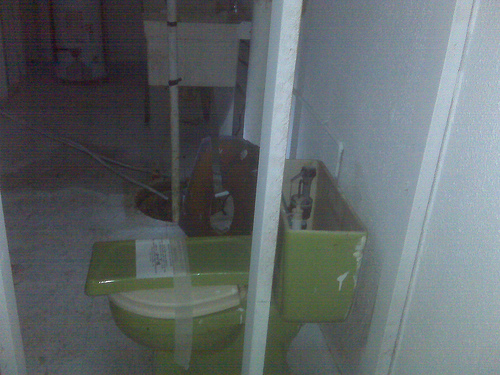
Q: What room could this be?
A: It is a bathroom.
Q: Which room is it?
A: It is a bathroom.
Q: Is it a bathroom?
A: Yes, it is a bathroom.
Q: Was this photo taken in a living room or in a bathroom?
A: It was taken at a bathroom.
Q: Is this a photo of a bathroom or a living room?
A: It is showing a bathroom.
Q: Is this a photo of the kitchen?
A: No, the picture is showing the bathroom.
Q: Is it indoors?
A: Yes, it is indoors.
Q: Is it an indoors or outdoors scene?
A: It is indoors.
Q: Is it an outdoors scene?
A: No, it is indoors.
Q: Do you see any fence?
A: No, there are no fences.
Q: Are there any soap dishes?
A: No, there are no soap dishes.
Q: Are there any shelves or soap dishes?
A: No, there are no soap dishes or shelves.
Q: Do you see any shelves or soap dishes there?
A: No, there are no soap dishes or shelves.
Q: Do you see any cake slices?
A: No, there are no cake slices.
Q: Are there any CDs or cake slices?
A: No, there are no cake slices or cds.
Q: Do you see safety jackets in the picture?
A: No, there are no safety jackets.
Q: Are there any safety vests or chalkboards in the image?
A: No, there are no safety vests or chalkboards.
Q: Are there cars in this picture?
A: No, there are no cars.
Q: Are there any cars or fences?
A: No, there are no cars or fences.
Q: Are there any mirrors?
A: No, there are no mirrors.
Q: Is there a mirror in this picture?
A: No, there are no mirrors.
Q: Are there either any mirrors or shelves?
A: No, there are no mirrors or shelves.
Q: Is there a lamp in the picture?
A: No, there are no lamps.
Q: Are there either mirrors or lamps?
A: No, there are no lamps or mirrors.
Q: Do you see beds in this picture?
A: No, there are no beds.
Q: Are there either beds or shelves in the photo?
A: No, there are no beds or shelves.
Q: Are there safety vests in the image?
A: No, there are no safety vests.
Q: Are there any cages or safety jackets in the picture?
A: No, there are no safety jackets or cages.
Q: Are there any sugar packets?
A: No, there are no sugar packets.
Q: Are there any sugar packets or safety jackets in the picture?
A: No, there are no sugar packets or safety jackets.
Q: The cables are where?
A: The cables are in the bathroom.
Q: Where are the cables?
A: The cables are in the bathroom.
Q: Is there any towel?
A: No, there are no towels.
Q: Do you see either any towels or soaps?
A: No, there are no towels or soaps.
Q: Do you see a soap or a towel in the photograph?
A: No, there are no towels or soaps.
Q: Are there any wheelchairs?
A: No, there are no wheelchairs.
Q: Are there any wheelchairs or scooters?
A: No, there are no wheelchairs or scooters.